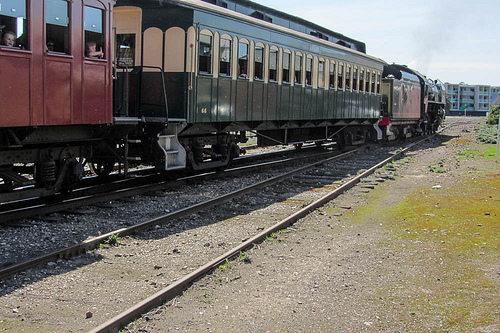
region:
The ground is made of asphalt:
[300, 245, 467, 311]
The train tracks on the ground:
[118, 190, 274, 295]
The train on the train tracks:
[20, 13, 463, 163]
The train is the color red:
[7, 59, 107, 121]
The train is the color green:
[178, 73, 328, 123]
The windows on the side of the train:
[196, 17, 391, 104]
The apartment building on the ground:
[443, 78, 497, 117]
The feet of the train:
[12, 137, 252, 177]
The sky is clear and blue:
[357, 3, 489, 56]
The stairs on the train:
[153, 119, 191, 178]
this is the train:
[45, 3, 307, 149]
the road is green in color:
[173, 8, 313, 123]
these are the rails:
[256, 163, 318, 223]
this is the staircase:
[160, 129, 189, 168]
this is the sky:
[417, 8, 484, 48]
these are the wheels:
[195, 131, 241, 166]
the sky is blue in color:
[406, 5, 484, 57]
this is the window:
[0, 15, 25, 48]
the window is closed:
[2, 3, 27, 45]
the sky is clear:
[416, 8, 479, 47]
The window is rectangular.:
[80, 3, 112, 65]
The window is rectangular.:
[195, 28, 216, 80]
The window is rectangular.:
[217, 30, 234, 80]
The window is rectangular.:
[233, 35, 251, 82]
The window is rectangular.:
[248, 39, 267, 84]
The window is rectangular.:
[266, 37, 282, 84]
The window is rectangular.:
[280, 48, 293, 86]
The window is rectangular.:
[291, 49, 304, 88]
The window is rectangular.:
[301, 46, 316, 90]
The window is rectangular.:
[39, 0, 78, 64]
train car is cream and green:
[114, 15, 431, 153]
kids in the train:
[6, 23, 119, 75]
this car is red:
[40, 40, 96, 140]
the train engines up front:
[383, 53, 451, 142]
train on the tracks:
[287, 26, 474, 168]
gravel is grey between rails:
[131, 122, 319, 257]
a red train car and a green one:
[53, 21, 283, 111]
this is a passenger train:
[21, 23, 394, 170]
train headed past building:
[219, 18, 499, 160]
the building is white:
[468, 80, 488, 123]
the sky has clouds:
[371, 7, 398, 35]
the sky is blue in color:
[376, 1, 412, 18]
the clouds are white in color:
[354, 5, 396, 35]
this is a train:
[16, 2, 450, 134]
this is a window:
[6, 5, 93, 51]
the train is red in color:
[48, 51, 103, 104]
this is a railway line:
[121, 222, 209, 280]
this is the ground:
[433, 200, 480, 239]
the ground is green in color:
[434, 203, 464, 232]